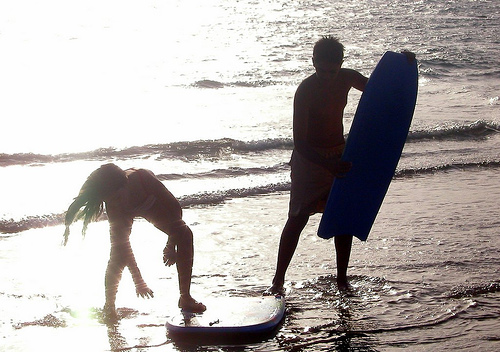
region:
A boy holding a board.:
[263, 34, 421, 293]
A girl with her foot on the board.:
[59, 156, 288, 340]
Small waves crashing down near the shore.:
[1, 112, 498, 237]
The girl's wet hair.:
[63, 159, 130, 245]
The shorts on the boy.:
[289, 139, 359, 216]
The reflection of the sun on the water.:
[4, 1, 230, 151]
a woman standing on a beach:
[57, 154, 211, 319]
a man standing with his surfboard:
[268, 33, 380, 293]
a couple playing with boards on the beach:
[54, 34, 451, 346]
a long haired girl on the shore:
[52, 143, 217, 317]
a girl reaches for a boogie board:
[60, 165, 290, 343]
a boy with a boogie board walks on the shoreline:
[267, 31, 419, 306]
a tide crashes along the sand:
[0, 65, 495, 250]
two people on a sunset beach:
[48, 28, 442, 346]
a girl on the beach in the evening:
[57, 158, 285, 340]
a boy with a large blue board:
[261, 28, 423, 298]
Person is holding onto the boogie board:
[265, 26, 450, 344]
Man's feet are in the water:
[266, 20, 428, 325]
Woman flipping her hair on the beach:
[60, 147, 286, 350]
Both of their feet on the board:
[144, 270, 321, 348]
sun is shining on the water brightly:
[12, 11, 499, 204]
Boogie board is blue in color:
[248, 20, 438, 293]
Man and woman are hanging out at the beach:
[28, 15, 465, 346]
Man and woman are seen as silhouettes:
[41, 30, 444, 337]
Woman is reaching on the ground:
[98, 211, 227, 343]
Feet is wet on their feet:
[16, 146, 469, 348]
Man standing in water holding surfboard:
[263, 34, 419, 300]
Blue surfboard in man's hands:
[317, 48, 420, 242]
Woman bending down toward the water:
[62, 162, 284, 336]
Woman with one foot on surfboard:
[63, 161, 285, 341]